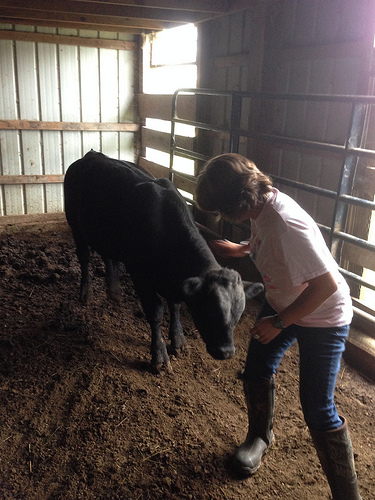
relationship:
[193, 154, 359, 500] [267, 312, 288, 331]
lady wearing watch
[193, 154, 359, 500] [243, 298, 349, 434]
lady wearing jeans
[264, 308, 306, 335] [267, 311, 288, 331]
wrist on watch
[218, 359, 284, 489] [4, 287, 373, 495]
boot used for farm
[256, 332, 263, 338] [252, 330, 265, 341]
ring on woman's finger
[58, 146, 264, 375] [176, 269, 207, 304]
cow has ear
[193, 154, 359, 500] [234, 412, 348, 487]
lady on boots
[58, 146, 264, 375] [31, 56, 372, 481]
cow in barn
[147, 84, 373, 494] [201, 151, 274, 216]
lady has hair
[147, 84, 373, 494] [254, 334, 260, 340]
lady wearing ring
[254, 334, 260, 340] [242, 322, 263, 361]
ring on her finger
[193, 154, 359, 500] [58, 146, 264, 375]
lady petting cow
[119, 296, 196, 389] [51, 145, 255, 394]
legs of cow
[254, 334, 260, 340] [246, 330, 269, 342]
ring on a finger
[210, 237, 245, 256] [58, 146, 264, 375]
hand above cow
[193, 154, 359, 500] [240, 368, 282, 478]
lady wearing boots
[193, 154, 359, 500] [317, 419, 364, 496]
lady wearing boots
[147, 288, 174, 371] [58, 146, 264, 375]
leg of cow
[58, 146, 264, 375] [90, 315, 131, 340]
cow standing in dirt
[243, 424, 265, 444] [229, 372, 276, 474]
gap on boot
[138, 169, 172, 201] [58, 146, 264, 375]
hump on cow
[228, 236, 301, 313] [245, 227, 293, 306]
design on shirt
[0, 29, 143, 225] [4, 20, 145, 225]
slats attached to wall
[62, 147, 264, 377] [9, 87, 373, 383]
cow in a pen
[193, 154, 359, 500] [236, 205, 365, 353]
lady wearing a shirt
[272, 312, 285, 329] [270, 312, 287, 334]
clock on wrist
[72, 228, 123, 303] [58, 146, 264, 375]
legs on cow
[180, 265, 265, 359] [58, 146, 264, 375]
head of a cow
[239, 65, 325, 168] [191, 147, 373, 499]
bars behind woman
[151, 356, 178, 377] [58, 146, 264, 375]
hoof on cow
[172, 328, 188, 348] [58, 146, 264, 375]
hoof on cow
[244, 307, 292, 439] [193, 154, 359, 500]
leg of lady